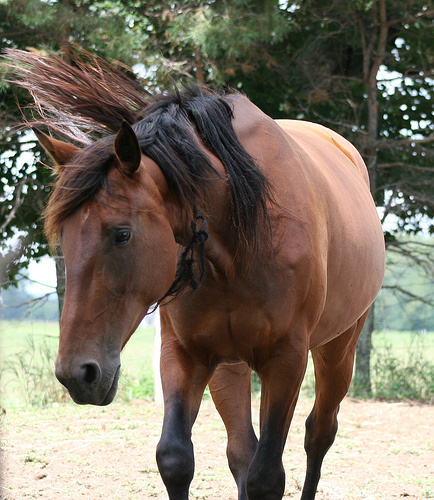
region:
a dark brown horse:
[3, 47, 386, 498]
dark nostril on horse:
[76, 360, 101, 390]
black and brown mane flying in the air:
[1, 43, 266, 246]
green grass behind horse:
[0, 321, 432, 412]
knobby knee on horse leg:
[155, 433, 197, 481]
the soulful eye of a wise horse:
[109, 225, 133, 249]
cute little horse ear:
[112, 119, 140, 176]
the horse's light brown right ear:
[31, 127, 79, 164]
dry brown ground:
[0, 393, 432, 497]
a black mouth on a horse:
[99, 358, 121, 405]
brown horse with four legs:
[54, 115, 365, 496]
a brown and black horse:
[30, 29, 392, 490]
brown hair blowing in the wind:
[29, 58, 131, 119]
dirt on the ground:
[50, 438, 116, 495]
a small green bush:
[383, 357, 432, 396]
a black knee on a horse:
[136, 411, 209, 495]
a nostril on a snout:
[65, 352, 102, 384]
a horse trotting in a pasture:
[42, 32, 395, 496]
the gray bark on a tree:
[360, 329, 376, 391]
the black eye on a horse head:
[108, 210, 163, 250]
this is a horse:
[2, 97, 377, 447]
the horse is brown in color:
[300, 175, 358, 238]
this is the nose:
[78, 358, 102, 387]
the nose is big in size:
[78, 358, 102, 382]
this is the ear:
[104, 114, 139, 179]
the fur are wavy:
[35, 65, 119, 117]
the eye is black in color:
[112, 222, 136, 244]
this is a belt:
[185, 209, 212, 277]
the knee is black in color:
[153, 443, 196, 483]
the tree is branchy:
[357, 61, 393, 130]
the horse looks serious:
[11, 131, 183, 403]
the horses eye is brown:
[73, 205, 141, 267]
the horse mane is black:
[99, 63, 284, 224]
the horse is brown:
[1, 44, 384, 399]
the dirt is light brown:
[40, 401, 403, 487]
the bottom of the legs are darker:
[117, 401, 358, 498]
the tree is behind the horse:
[274, 3, 432, 392]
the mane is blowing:
[0, 28, 222, 193]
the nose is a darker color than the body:
[37, 338, 124, 414]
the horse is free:
[0, 96, 401, 451]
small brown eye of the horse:
[93, 217, 157, 258]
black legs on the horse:
[144, 387, 334, 497]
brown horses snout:
[40, 208, 135, 415]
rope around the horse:
[130, 197, 247, 342]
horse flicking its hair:
[5, 37, 306, 242]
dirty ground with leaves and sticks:
[350, 407, 429, 484]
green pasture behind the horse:
[0, 301, 54, 405]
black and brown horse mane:
[3, 56, 296, 237]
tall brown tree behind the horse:
[342, 9, 394, 428]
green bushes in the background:
[362, 339, 432, 407]